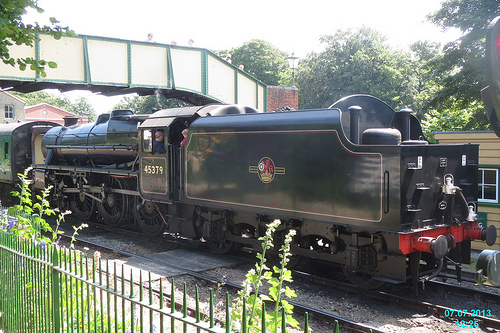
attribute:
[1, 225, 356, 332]
fence — short , green, metal, in forefront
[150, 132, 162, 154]
man — wearing blue shirt, white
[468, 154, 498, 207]
window — white , small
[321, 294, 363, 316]
pebbles — small, grey, stone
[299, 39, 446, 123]
trees — green, leafy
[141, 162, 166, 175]
numbers — 45379, white, large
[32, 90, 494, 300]
train — big, black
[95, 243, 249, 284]
walk way — wood, grey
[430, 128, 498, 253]
building — tan, sided, short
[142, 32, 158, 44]
people — is white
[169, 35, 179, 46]
people — is white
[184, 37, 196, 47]
people — is white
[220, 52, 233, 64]
people — is white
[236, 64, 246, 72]
people — is white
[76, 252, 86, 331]
rod — metal, green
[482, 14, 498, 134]
light — metal, red, tall, black, grey, parallel 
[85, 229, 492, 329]
tracks — metal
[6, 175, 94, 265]
green plants — tall, flowering , are weeds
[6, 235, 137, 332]
fence — green, metal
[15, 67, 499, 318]
train — is black, has white stripes, has red stripes, is large, has multiple cars, has a red bumper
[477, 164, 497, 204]
window — is trimmed, is paned, small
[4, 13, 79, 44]
tree limb — tall, long, green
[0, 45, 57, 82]
tree limb — tall, long, green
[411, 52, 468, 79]
tree limb — green, tall, long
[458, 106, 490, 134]
tree limb — green, tall, long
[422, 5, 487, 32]
tree limb — green, tall, long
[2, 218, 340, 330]
fence — short, green, metal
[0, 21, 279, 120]
bridge — green, white, short, tall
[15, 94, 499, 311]
train — large, black, with white lettering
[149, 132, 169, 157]
driver — is white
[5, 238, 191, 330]
gate — green, metal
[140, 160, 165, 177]
number — is white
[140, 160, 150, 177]
number — is white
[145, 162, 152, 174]
number — is white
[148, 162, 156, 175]
number — is white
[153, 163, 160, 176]
number — is white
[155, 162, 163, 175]
number — is white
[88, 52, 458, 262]
train — has a red bumper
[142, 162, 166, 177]
45379 — number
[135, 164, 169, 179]
number — white, large, identifying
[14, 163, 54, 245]
green leafy — leafy , sprouting , tall